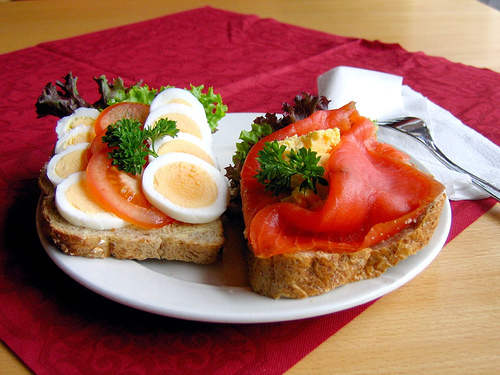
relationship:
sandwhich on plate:
[54, 87, 216, 250] [68, 69, 441, 321]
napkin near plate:
[334, 66, 486, 168] [68, 69, 441, 321]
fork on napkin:
[398, 121, 479, 182] [334, 66, 486, 168]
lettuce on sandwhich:
[195, 86, 228, 122] [54, 87, 216, 250]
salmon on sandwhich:
[253, 123, 403, 231] [54, 87, 216, 250]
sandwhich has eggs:
[54, 87, 216, 250] [282, 134, 369, 157]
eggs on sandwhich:
[282, 134, 369, 157] [54, 87, 216, 250]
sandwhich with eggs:
[54, 87, 216, 250] [282, 134, 369, 157]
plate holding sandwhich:
[68, 69, 441, 321] [54, 87, 216, 250]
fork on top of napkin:
[398, 121, 479, 182] [334, 66, 486, 168]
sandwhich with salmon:
[54, 87, 216, 250] [253, 123, 403, 231]